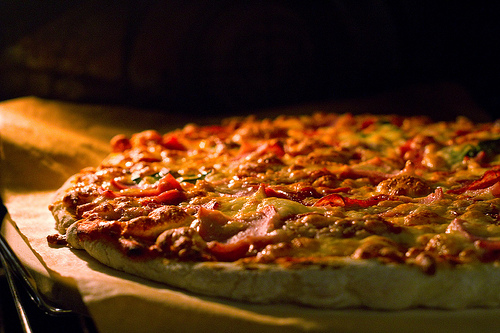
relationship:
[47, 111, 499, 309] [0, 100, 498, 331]
cheese on table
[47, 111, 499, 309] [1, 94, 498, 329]
cheese on cloth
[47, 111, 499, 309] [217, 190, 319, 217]
cheese with cheese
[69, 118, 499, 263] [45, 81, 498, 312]
cheese on pizza